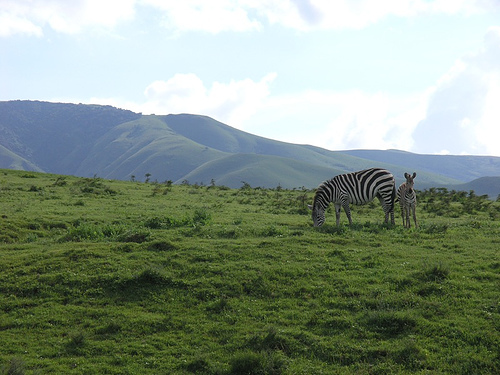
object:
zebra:
[312, 168, 397, 228]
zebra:
[398, 170, 420, 228]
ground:
[0, 169, 500, 374]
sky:
[0, 0, 500, 160]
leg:
[379, 190, 391, 224]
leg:
[332, 204, 340, 226]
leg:
[343, 204, 354, 226]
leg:
[388, 202, 397, 224]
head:
[314, 200, 331, 226]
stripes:
[357, 168, 367, 201]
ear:
[413, 171, 418, 181]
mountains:
[1, 101, 500, 375]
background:
[0, 0, 497, 374]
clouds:
[0, 0, 500, 155]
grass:
[3, 169, 500, 375]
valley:
[26, 144, 161, 181]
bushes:
[0, 171, 499, 375]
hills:
[0, 98, 499, 201]